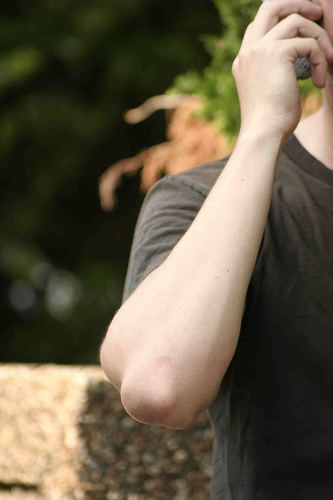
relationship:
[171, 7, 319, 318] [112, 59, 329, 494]
hand on person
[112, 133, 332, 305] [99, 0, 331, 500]
shirt on man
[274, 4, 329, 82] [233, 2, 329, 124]
cellphone in hand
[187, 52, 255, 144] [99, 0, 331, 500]
trees behind man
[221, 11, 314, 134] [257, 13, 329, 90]
man talking on cellphone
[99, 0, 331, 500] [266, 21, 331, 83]
man on cellphone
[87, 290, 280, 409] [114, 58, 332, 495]
elbow on man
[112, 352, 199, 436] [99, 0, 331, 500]
elbow on man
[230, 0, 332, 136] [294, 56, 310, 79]
hand holding cellphone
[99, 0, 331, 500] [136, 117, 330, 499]
man wearing shirt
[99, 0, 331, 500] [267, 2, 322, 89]
man holding phone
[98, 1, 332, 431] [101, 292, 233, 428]
arm bent at elbow